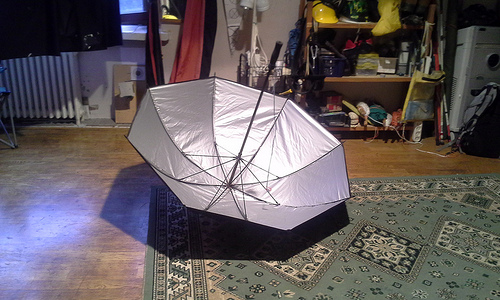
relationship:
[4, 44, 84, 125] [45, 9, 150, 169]
radiator on wall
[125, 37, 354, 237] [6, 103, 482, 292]
umbrella on floor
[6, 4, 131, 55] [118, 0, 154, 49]
curtain covering window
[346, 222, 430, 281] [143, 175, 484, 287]
diamond on rug